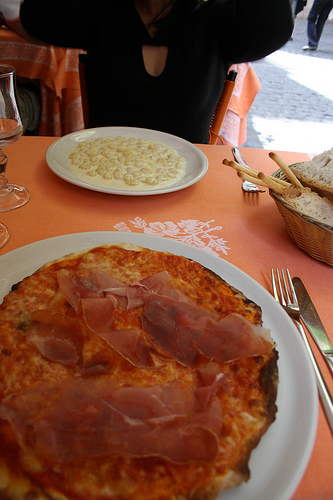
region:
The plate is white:
[43, 126, 214, 197]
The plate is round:
[41, 123, 214, 193]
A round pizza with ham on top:
[2, 240, 295, 484]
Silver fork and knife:
[258, 250, 329, 431]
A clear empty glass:
[2, 69, 40, 217]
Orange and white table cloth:
[6, 33, 102, 123]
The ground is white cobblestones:
[250, 43, 330, 146]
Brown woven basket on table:
[259, 153, 329, 254]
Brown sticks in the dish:
[227, 152, 304, 205]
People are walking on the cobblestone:
[281, 2, 328, 57]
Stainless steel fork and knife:
[256, 267, 332, 414]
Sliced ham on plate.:
[62, 306, 220, 454]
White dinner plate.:
[267, 401, 319, 499]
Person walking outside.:
[287, 0, 329, 70]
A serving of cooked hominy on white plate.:
[74, 131, 183, 189]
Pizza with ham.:
[8, 256, 281, 492]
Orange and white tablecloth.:
[182, 64, 237, 247]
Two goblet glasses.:
[0, 62, 23, 263]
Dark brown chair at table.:
[17, 1, 288, 137]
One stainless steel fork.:
[225, 147, 264, 199]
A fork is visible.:
[266, 248, 323, 340]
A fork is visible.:
[254, 270, 304, 337]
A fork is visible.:
[279, 247, 302, 325]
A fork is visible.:
[261, 283, 313, 353]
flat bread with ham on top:
[3, 240, 280, 496]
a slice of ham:
[94, 268, 179, 305]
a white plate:
[279, 345, 312, 484]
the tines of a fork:
[270, 267, 301, 306]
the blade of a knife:
[295, 272, 332, 341]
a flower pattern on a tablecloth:
[111, 217, 223, 233]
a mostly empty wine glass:
[1, 66, 30, 212]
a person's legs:
[305, 1, 331, 43]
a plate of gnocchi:
[44, 122, 207, 196]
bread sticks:
[256, 152, 300, 198]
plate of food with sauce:
[57, 126, 207, 200]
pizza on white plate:
[25, 245, 284, 451]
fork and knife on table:
[261, 257, 330, 386]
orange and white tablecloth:
[77, 197, 258, 268]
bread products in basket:
[233, 142, 330, 251]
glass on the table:
[2, 67, 60, 213]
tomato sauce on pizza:
[183, 259, 282, 420]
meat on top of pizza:
[59, 269, 274, 392]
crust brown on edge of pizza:
[164, 254, 286, 411]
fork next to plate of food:
[139, 136, 260, 205]